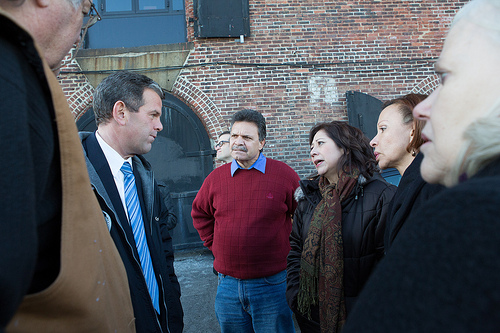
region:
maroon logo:
[248, 181, 280, 222]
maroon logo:
[262, 177, 292, 227]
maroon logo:
[265, 187, 283, 222]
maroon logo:
[244, 174, 295, 251]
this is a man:
[203, 92, 281, 331]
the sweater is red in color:
[218, 177, 283, 278]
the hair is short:
[236, 110, 251, 119]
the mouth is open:
[312, 158, 326, 168]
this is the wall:
[284, 0, 357, 94]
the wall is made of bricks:
[281, 28, 348, 87]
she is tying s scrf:
[311, 185, 343, 248]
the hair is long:
[345, 132, 367, 162]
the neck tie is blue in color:
[128, 202, 141, 219]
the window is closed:
[109, 5, 178, 45]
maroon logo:
[260, 171, 320, 239]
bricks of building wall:
[269, 11, 353, 68]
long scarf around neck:
[287, 178, 357, 305]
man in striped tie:
[106, 69, 176, 281]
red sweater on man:
[185, 153, 300, 280]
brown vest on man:
[31, 90, 123, 312]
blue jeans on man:
[202, 262, 293, 331]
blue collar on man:
[221, 153, 268, 182]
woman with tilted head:
[302, 114, 369, 186]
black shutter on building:
[187, 2, 262, 52]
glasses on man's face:
[70, 2, 107, 47]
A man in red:
[229, 105, 329, 322]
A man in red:
[260, 191, 317, 321]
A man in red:
[225, 97, 267, 194]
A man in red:
[226, 119, 293, 259]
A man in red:
[187, 114, 235, 208]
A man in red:
[247, 191, 285, 325]